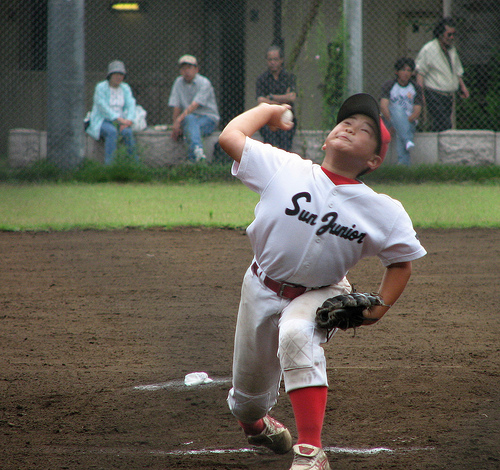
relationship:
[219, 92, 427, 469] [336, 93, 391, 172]
boy wearing cap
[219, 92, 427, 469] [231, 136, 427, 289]
boy wearing shirt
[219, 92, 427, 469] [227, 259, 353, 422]
boy wearing pants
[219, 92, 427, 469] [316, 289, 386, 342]
boy holding glove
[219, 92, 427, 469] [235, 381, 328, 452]
boy wearing socks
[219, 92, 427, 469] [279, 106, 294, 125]
boy throwing ball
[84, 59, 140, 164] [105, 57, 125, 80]
spectators wearing hat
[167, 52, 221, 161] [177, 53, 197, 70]
man wearing cap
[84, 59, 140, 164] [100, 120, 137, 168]
spectators wearing jeans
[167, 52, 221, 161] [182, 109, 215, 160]
man wearing jeans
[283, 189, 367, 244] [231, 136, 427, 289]
sun junior on front of shirt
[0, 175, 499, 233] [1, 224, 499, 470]
grass next to field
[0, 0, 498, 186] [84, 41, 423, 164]
fence in front of spectators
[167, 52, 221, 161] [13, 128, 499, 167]
man sitting on wall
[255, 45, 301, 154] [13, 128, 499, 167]
man sitting on wall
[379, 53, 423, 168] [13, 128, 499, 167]
man sitting on wall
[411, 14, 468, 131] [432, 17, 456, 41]
man has hair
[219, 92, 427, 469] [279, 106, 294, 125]
boy holding ball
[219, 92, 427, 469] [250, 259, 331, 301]
boy wearing belt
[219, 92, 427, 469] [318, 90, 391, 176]
boy has head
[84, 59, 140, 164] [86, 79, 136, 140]
spectators wearing jacket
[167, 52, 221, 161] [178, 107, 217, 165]
man has legs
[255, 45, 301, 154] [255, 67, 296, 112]
man wearing shirt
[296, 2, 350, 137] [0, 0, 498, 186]
vines growing on fence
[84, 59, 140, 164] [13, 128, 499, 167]
spectators sitting on wall